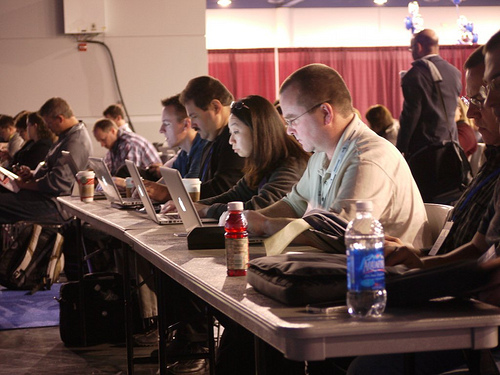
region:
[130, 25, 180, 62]
this is the wall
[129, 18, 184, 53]
the wall is made of stone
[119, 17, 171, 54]
the wall is white in color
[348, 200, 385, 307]
this is a bottle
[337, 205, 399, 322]
the bottle is made of plastic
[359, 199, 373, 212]
the lid is white in color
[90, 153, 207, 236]
these are some laptops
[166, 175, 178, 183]
the laptop is grey in color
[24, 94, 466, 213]
these are several people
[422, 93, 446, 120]
the coat is black in color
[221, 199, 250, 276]
Bottle of juice on table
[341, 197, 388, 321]
Bottle of Aquafina water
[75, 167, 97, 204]
Cup of coffee on table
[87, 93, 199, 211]
Man on laptop computer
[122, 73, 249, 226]
Man on laptop computer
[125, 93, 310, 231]
Woman on laptop computer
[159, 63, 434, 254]
Man on laptop computer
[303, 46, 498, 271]
Man sitting at table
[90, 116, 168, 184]
Man in a plaid shirt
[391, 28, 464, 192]
Man with balding hair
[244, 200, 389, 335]
a water is kept beside the bag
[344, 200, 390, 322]
a water bottle with white lid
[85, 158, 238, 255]
laptops are open on the table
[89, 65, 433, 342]
people are sitting in front of the lap top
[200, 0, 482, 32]
ceiling light are turned on and glowing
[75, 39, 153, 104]
a black power cable on the wall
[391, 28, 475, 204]
the guy is standing with his bag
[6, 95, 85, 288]
the guy is sitting on a chair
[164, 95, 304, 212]
the woman is sitting with the loose hair do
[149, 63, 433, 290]
a woman is sitting in between two men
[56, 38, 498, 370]
people sitting at a table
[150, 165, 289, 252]
silver laptop sitting open on the table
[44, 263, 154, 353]
bag under the table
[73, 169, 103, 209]
cup of coffee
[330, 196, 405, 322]
clear plastic water bottle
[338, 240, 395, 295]
blue label around the bottle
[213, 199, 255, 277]
red liquid in the bottle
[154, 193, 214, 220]
hand hovering over the keyboard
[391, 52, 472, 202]
bag hanging down from the shoulder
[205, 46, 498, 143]
red curtains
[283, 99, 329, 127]
The man is wearing glasses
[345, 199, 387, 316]
A bottle of water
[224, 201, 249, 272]
A bottle of a fruit drink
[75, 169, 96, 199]
A paper cup near the computer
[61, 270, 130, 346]
A suitcase beneath the table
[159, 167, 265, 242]
An Apple laptop on the desk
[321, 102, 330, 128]
The left ear of the man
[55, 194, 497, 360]
Tables beneath the laptops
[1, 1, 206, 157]
A wall in the room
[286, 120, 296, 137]
The nose of the man